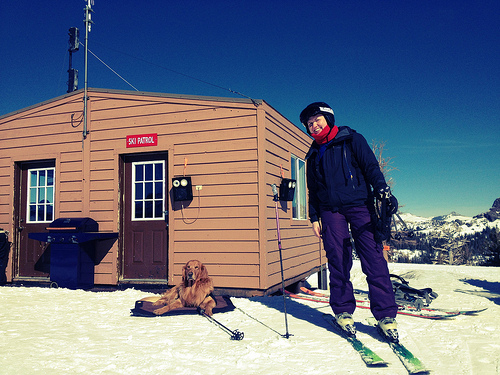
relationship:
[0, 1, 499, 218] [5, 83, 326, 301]
sky above building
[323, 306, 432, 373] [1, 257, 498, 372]
skis are on ground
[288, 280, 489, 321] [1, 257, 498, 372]
skis are on ground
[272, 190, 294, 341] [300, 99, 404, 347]
ski pole beside person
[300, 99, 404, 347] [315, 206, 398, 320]
person wearing pants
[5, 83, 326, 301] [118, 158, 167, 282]
building has a door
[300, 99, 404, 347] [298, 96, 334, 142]
person has a head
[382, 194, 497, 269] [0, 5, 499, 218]
mountains are in background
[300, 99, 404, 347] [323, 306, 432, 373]
person standing on skis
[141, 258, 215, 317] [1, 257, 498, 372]
dog laying on ground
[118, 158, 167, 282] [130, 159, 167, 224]
door has a window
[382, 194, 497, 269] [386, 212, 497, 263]
mountains are covered with snow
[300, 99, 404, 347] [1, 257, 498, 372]
person standing on snow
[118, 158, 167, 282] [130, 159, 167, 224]
door has window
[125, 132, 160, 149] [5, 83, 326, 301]
sign on building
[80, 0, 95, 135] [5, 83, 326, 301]
pole on house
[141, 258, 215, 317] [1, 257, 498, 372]
dog on ground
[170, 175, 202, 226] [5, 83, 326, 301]
meter on side of th building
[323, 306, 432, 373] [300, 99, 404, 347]
skis are on woman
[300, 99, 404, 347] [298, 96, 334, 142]
woman has a head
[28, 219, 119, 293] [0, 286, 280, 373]
grill sitting on snow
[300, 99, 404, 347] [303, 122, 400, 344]
woman wearing ski clothes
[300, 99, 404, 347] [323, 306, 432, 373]
person wearing skis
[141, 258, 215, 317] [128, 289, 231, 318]
dog sitting on mat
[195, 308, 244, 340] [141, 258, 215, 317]
ski pole close to dog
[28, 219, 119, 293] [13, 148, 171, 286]
grill between doors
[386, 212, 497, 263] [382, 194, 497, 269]
snow on mountains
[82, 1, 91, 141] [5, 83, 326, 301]
antennae on building